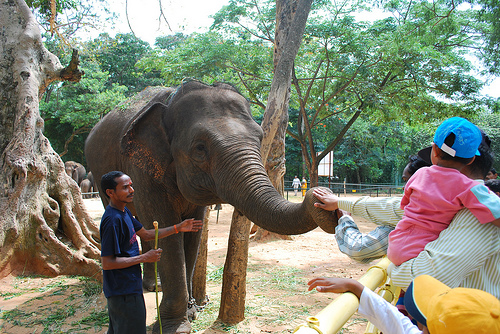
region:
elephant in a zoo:
[83, 67, 352, 330]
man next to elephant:
[78, 157, 208, 330]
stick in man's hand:
[140, 216, 173, 331]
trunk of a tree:
[3, 7, 90, 287]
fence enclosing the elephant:
[336, 130, 401, 187]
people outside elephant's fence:
[300, 108, 492, 330]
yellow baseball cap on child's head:
[404, 267, 496, 327]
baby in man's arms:
[380, 104, 492, 279]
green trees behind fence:
[310, 20, 407, 180]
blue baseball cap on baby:
[421, 110, 494, 170]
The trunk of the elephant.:
[237, 153, 344, 236]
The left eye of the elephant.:
[191, 142, 206, 152]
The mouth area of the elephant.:
[190, 181, 225, 206]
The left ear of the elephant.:
[120, 106, 170, 176]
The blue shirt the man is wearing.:
[100, 205, 150, 287]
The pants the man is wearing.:
[101, 295, 137, 330]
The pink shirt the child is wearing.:
[385, 166, 490, 248]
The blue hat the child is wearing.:
[430, 115, 485, 155]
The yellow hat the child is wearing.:
[400, 277, 498, 332]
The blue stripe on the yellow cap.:
[405, 281, 428, 324]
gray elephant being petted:
[80, 78, 330, 320]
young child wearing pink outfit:
[382, 123, 499, 264]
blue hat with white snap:
[435, 117, 482, 156]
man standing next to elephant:
[100, 170, 205, 331]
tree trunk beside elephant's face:
[222, 8, 284, 323]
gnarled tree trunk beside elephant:
[3, 4, 99, 271]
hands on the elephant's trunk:
[310, 184, 357, 222]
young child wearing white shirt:
[313, 275, 498, 332]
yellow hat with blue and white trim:
[401, 275, 496, 332]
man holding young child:
[410, 133, 499, 295]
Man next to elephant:
[90, 171, 175, 332]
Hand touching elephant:
[310, 173, 415, 239]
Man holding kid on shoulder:
[391, 135, 496, 260]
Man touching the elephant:
[90, 166, 210, 261]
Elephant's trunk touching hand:
[211, 130, 359, 235]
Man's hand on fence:
[305, 265, 385, 315]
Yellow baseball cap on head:
[405, 266, 492, 327]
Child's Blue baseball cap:
[401, 100, 482, 166]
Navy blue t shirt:
[85, 206, 155, 297]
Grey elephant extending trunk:
[67, 58, 305, 316]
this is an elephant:
[140, 73, 259, 217]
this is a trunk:
[239, 172, 306, 245]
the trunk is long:
[242, 167, 294, 229]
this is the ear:
[113, 95, 168, 158]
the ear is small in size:
[114, 106, 174, 163]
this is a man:
[92, 161, 148, 321]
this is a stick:
[147, 218, 168, 245]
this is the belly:
[85, 115, 117, 162]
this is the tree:
[0, 36, 57, 167]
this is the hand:
[305, 270, 346, 294]